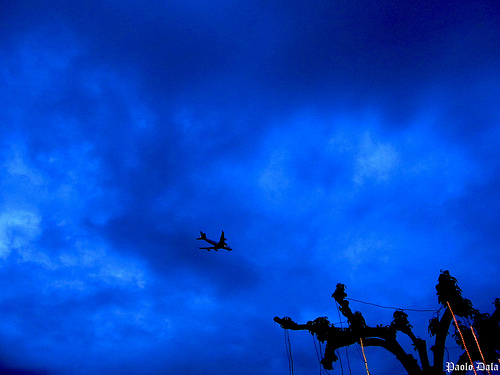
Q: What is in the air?
A: A plane.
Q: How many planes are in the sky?
A: One.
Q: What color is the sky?
A: Dark blue.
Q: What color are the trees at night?
A: Black.